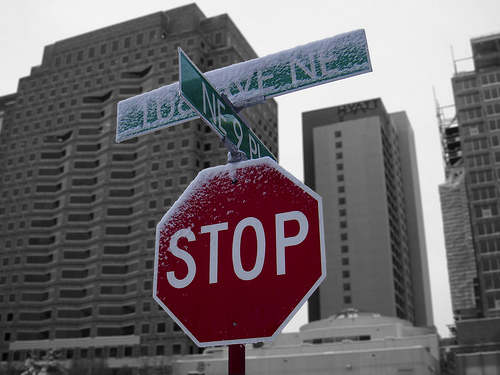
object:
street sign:
[115, 29, 373, 150]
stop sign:
[151, 155, 324, 348]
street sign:
[177, 46, 277, 163]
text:
[201, 81, 219, 121]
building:
[301, 98, 438, 325]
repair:
[437, 43, 482, 321]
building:
[430, 30, 498, 374]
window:
[333, 129, 342, 138]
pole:
[228, 344, 247, 375]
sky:
[1, 1, 500, 341]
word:
[336, 103, 351, 117]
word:
[166, 224, 204, 289]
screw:
[222, 146, 244, 164]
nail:
[231, 176, 237, 185]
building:
[0, 7, 279, 374]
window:
[110, 169, 137, 180]